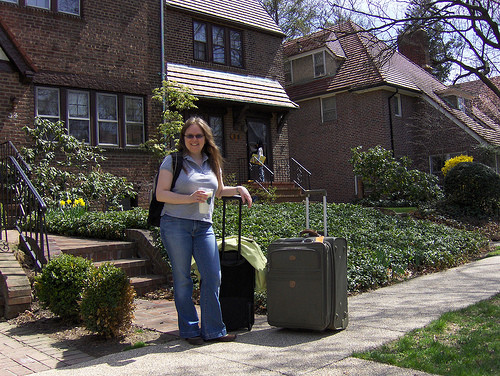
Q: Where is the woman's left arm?
A: Resting on a suitcase handle.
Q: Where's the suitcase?
A: Ground.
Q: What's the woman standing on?
A: Sidewalk.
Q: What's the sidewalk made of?
A: Cement.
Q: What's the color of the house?
A: Brown.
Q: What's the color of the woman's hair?
A: Brown.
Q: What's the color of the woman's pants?
A: Blue.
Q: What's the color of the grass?
A: Green.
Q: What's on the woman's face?
A: Sunglasses.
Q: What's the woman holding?
A: Cup.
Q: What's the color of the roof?
A: Brown.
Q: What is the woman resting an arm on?
A: A suitcase handle.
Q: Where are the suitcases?
A: On the sidewalk next to the woman.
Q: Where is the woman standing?
A: On the sidewalk outside the house.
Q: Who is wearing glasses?
A: The woman.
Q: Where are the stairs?
A: Behind the woman.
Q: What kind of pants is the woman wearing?
A: Blue jeans.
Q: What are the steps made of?
A: Bricks.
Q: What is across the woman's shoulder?
A: A bag.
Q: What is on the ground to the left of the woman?
A: Two small plants.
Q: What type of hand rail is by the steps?
A: Wrought iron.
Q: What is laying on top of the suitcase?
A: Sweater.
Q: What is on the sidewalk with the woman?
A: 2 suitcases.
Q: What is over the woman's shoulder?
A: Backpack.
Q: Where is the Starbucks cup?
A: Her hand.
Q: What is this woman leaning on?
A: A luggage handle.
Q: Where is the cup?
A: In her hand.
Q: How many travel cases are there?
A: Two.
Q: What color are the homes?
A: Brown.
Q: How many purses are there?
A: One.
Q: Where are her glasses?
A: On her face.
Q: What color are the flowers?
A: Yellow.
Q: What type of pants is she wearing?
A: Jeans.